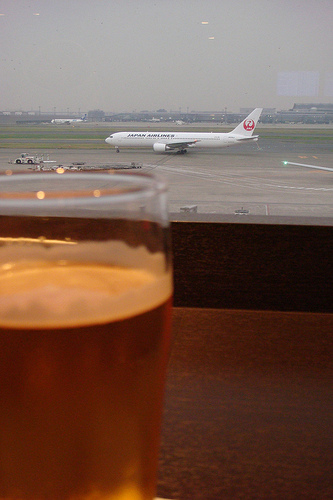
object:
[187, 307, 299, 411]
wood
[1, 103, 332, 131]
scenery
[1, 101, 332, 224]
airport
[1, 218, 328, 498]
table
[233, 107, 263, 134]
wing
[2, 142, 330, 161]
runway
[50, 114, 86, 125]
plane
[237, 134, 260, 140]
wing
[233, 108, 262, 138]
tail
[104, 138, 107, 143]
nose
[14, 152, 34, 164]
car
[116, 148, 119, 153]
wheels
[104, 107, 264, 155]
airplane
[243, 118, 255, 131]
logo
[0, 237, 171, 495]
beer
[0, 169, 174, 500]
glass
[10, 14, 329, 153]
background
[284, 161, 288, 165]
light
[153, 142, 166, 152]
engine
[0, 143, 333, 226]
ground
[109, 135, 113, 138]
cockpit